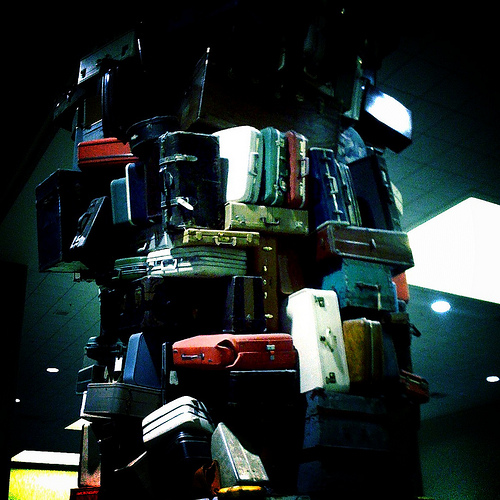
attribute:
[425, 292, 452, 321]
light — round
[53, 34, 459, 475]
suitcase — white, red, mustard, jumbo, yellow, black, stacked, tan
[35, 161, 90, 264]
trunk — black, green, wooden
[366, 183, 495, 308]
light — recessed, circular, small, large, on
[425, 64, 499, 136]
tile — white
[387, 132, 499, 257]
ceiling — tiled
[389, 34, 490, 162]
background — yellow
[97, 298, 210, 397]
luggage — blue, black